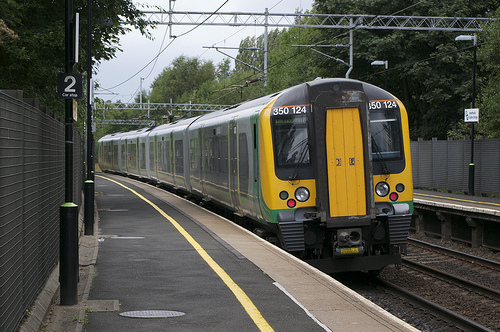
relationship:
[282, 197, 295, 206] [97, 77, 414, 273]
front light of passenger train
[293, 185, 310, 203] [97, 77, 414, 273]
front light of passenger train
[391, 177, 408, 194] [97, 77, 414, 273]
front light of passenger train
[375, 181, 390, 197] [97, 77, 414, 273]
front light of passenger train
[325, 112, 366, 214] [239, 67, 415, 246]
door of train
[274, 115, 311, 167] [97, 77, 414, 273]
window of passenger train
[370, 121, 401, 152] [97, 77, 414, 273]
window of passenger train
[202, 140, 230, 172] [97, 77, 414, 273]
window of passenger train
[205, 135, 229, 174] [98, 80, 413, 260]
window of train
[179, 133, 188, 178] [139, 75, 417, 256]
window of train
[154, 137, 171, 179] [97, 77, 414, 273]
window of passenger train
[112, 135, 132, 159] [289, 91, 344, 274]
window of train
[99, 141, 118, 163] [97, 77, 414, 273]
window of passenger train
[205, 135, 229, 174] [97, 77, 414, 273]
window of passenger train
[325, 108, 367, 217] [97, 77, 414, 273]
door on passenger train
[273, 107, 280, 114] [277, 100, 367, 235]
number of train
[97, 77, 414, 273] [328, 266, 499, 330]
passenger train on track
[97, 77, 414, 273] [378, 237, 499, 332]
passenger train on track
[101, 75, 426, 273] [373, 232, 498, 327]
passenger train on track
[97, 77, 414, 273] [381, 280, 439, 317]
passenger train on train track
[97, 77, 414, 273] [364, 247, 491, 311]
passenger train on track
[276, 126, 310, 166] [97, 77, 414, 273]
window on passenger train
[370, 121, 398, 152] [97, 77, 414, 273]
window on passenger train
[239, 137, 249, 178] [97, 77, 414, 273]
window on passenger train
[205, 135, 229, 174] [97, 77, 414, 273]
window on passenger train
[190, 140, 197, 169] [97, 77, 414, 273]
window on passenger train